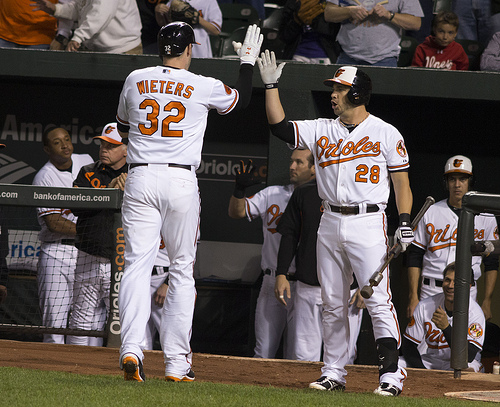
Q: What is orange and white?
A: The jersey.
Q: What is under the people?
A: Dirt and grass.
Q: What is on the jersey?
A: Team name.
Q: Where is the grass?
A: On the ground.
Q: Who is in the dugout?
A: Some players.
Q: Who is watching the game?
A: Some people.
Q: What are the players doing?
A: High five.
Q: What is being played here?
A: Baseball.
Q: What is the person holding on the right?
A: Bat.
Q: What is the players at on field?
A: A dugout.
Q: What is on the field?
A: Grass.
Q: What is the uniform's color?
A: White.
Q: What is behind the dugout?
A: Audiences.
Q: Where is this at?
A: Baseball field.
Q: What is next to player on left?
A: Fence.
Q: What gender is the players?
A: Males.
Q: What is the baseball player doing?
A: Raising his hand.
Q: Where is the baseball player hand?
A: Up.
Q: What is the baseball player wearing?
A: A helmet.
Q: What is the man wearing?
A: A black shirt.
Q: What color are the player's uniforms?
A: White.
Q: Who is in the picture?
A: Baseball players.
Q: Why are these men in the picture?
A: To play baseball.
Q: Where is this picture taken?
A: The dugout.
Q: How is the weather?
A: Sunny.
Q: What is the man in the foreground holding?
A: A bat.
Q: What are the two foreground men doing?
A: High fiving.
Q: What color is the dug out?
A: Brown.